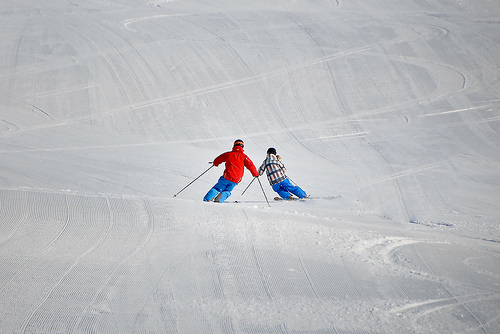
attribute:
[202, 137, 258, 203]
man — skiing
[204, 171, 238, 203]
pants — blue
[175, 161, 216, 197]
pole — black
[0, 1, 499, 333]
slope — snowy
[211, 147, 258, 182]
coat — red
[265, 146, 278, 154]
hat — black